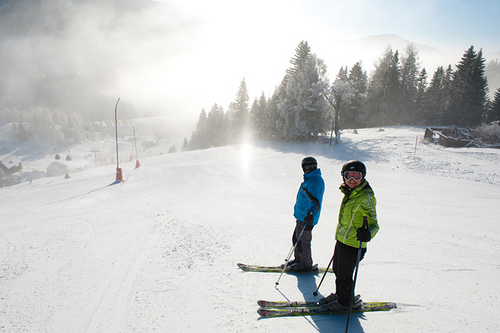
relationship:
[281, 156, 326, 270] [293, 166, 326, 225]
skier inside of jacket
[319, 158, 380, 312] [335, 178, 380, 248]
skier inside of jacket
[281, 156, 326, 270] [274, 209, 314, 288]
skier holding ski pole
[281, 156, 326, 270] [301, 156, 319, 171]
skier wearing cap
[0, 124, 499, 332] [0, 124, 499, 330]
snow on top of ground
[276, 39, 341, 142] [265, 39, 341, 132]
pine tree covered in snow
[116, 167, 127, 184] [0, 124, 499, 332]
cone sitting in snow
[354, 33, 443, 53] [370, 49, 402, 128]
mountain behind tree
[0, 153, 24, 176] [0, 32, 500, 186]
house below mountain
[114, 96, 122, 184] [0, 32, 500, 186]
pole sitting on mountain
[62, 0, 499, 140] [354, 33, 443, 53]
cloud above mountain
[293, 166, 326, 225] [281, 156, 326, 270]
jacket worn on skier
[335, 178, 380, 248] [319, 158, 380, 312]
jacket worn on skier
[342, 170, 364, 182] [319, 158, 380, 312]
ski goggles worn on skier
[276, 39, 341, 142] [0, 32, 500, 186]
pine tree sitting on mountain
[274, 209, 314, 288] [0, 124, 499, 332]
ski pole touching snow